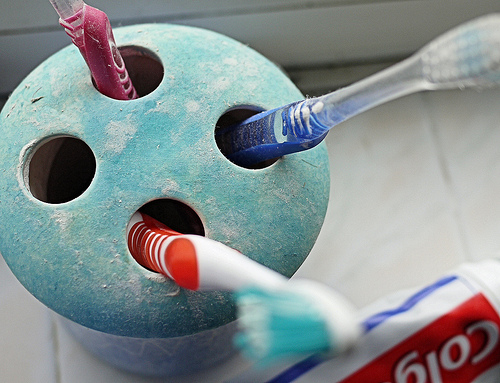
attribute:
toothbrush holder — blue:
[2, 22, 334, 343]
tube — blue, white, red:
[282, 276, 497, 379]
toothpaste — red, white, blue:
[223, 255, 499, 381]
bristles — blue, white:
[241, 294, 291, 351]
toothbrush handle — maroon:
[47, 1, 140, 100]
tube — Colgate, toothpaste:
[324, 253, 491, 381]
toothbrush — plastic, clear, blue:
[216, 13, 498, 165]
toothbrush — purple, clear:
[61, 11, 494, 154]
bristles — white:
[228, 285, 330, 369]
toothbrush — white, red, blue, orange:
[121, 212, 353, 366]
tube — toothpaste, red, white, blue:
[364, 271, 496, 379]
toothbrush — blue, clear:
[114, 144, 392, 376]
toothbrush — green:
[116, 196, 356, 366]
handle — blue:
[230, 90, 331, 152]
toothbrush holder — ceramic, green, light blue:
[0, 22, 330, 375]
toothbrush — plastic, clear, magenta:
[50, 2, 142, 97]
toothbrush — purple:
[45, 0, 136, 99]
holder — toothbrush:
[2, 19, 332, 381]